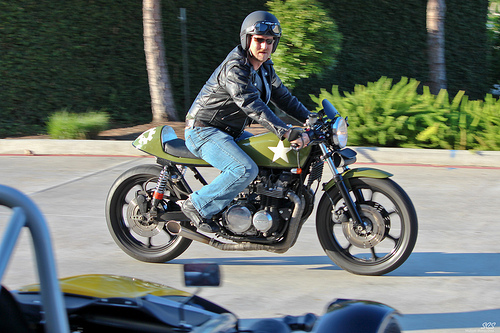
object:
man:
[182, 9, 329, 228]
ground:
[0, 153, 500, 331]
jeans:
[180, 126, 256, 220]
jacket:
[181, 44, 314, 139]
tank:
[241, 125, 311, 170]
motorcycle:
[106, 98, 417, 276]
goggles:
[251, 36, 276, 45]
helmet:
[238, 9, 285, 52]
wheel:
[311, 168, 424, 277]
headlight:
[330, 116, 349, 148]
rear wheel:
[103, 164, 199, 265]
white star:
[266, 140, 299, 166]